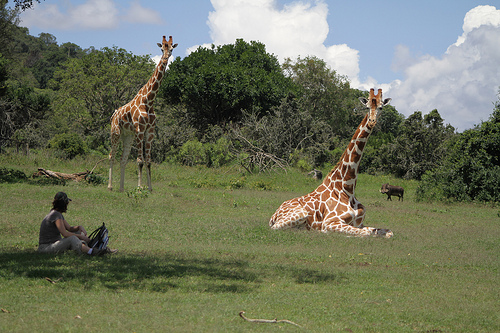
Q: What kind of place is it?
A: It is a field.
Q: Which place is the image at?
A: It is at the field.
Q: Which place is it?
A: It is a field.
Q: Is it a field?
A: Yes, it is a field.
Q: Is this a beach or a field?
A: It is a field.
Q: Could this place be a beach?
A: No, it is a field.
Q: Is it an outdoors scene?
A: Yes, it is outdoors.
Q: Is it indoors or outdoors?
A: It is outdoors.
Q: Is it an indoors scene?
A: No, it is outdoors.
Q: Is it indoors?
A: No, it is outdoors.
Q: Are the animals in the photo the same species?
A: No, they are giraffes and pigs.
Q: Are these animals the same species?
A: No, there are both giraffes and pigs.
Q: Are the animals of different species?
A: Yes, they are giraffes and pigs.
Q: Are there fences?
A: No, there are no fences.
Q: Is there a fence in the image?
A: No, there are no fences.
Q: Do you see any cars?
A: No, there are no cars.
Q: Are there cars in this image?
A: No, there are no cars.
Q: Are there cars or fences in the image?
A: No, there are no cars or fences.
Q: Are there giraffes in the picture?
A: Yes, there is a giraffe.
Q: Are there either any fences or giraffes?
A: Yes, there is a giraffe.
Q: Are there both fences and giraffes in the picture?
A: No, there is a giraffe but no fences.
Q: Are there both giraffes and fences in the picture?
A: No, there is a giraffe but no fences.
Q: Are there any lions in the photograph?
A: No, there are no lions.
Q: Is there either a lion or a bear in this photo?
A: No, there are no lions or bears.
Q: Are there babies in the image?
A: No, there are no babies.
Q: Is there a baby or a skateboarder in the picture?
A: No, there are no babies or skateboarders.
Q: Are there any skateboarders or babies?
A: No, there are no babies or skateboarders.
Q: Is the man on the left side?
A: Yes, the man is on the left of the image.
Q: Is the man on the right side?
A: No, the man is on the left of the image.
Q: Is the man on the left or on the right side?
A: The man is on the left of the image.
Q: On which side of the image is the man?
A: The man is on the left of the image.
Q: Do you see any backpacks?
A: Yes, there is a backpack.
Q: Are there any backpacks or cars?
A: Yes, there is a backpack.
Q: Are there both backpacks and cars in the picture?
A: No, there is a backpack but no cars.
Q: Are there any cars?
A: No, there are no cars.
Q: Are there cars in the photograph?
A: No, there are no cars.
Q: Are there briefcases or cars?
A: No, there are no cars or briefcases.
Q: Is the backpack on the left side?
A: Yes, the backpack is on the left of the image.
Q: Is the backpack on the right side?
A: No, the backpack is on the left of the image.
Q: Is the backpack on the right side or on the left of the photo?
A: The backpack is on the left of the image.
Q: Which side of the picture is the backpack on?
A: The backpack is on the left of the image.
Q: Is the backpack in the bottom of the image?
A: Yes, the backpack is in the bottom of the image.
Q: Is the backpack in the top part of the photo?
A: No, the backpack is in the bottom of the image.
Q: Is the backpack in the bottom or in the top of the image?
A: The backpack is in the bottom of the image.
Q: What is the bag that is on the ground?
A: The bag is a backpack.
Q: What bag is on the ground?
A: The bag is a backpack.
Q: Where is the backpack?
A: The backpack is on the ground.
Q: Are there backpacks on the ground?
A: Yes, there is a backpack on the ground.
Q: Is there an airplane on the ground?
A: No, there is a backpack on the ground.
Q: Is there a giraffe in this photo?
A: Yes, there is a giraffe.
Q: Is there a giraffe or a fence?
A: Yes, there is a giraffe.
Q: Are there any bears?
A: No, there are no bears.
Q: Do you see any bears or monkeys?
A: No, there are no bears or monkeys.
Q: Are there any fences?
A: No, there are no fences.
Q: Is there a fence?
A: No, there are no fences.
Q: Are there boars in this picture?
A: Yes, there is a boar.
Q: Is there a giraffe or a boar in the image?
A: Yes, there is a boar.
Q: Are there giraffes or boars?
A: Yes, there is a boar.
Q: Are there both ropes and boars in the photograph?
A: No, there is a boar but no ropes.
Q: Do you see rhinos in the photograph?
A: No, there are no rhinos.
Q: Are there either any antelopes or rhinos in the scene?
A: No, there are no rhinos or antelopes.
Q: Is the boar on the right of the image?
A: Yes, the boar is on the right of the image.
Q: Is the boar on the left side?
A: No, the boar is on the right of the image.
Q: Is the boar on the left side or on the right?
A: The boar is on the right of the image.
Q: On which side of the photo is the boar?
A: The boar is on the right of the image.